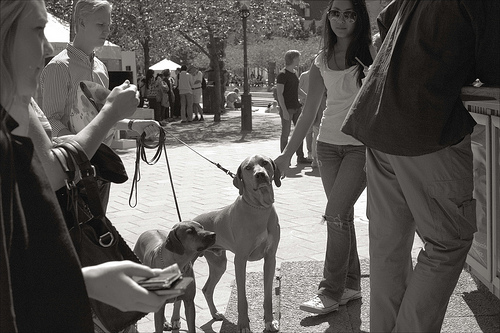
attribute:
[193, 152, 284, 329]
dog — tall, friends, big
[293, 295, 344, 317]
shoe — white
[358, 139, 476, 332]
jeans — wrinkly, khaki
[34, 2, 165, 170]
man — human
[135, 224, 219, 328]
dog — small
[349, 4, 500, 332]
man — standing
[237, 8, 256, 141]
light post — off, black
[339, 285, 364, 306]
shoe — white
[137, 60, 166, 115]
person — buying refreshments, milling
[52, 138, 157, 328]
purse — big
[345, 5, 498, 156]
shirt — black